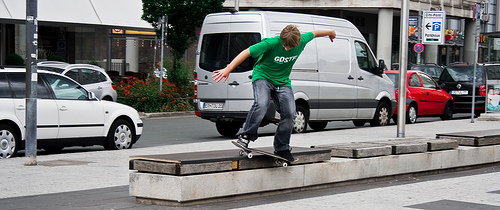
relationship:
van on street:
[194, 11, 395, 129] [6, 58, 498, 166]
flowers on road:
[120, 59, 172, 112] [147, 110, 198, 136]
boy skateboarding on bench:
[210, 24, 335, 161] [142, 164, 321, 191]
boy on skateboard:
[210, 24, 335, 161] [235, 138, 290, 169]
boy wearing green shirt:
[210, 24, 335, 161] [248, 32, 315, 88]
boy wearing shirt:
[218, 9, 334, 178] [259, 32, 293, 84]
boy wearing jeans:
[210, 24, 335, 161] [238, 79, 296, 153]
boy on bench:
[210, 24, 335, 161] [124, 139, 498, 208]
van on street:
[194, 11, 396, 137] [12, 91, 488, 151]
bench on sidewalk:
[126, 145, 336, 207] [13, 113, 494, 207]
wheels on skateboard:
[236, 151, 242, 155] [231, 140, 291, 170]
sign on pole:
[422, 11, 446, 44] [392, 4, 442, 144]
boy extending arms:
[210, 24, 335, 161] [206, 21, 352, 90]